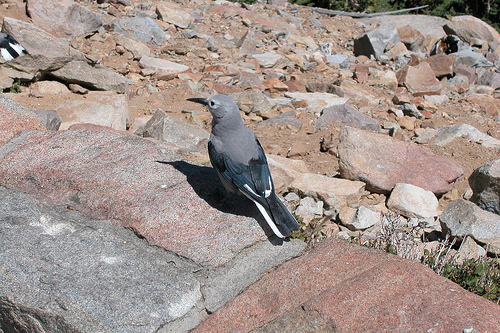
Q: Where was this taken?
A: On a pile of rocks.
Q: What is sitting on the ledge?
A: A bird.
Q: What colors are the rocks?
A: Shades of brown and red.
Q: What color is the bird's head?
A: Gray.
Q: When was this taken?
A: During the day.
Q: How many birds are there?
A: One.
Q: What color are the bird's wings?
A: Dark blue and white.